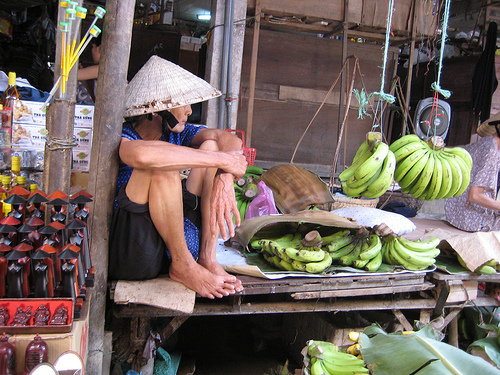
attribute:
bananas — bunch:
[330, 129, 400, 202]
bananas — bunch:
[331, 124, 401, 211]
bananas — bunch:
[330, 124, 406, 207]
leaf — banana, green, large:
[384, 127, 482, 204]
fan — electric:
[412, 88, 459, 148]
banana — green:
[298, 333, 379, 373]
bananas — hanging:
[383, 120, 475, 201]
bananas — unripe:
[323, 117, 405, 207]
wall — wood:
[188, 3, 414, 186]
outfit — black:
[105, 169, 227, 287]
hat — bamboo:
[113, 51, 230, 121]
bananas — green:
[262, 232, 478, 302]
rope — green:
[352, 43, 432, 115]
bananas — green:
[263, 217, 450, 243]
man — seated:
[115, 50, 277, 327]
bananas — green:
[398, 134, 481, 192]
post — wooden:
[91, 35, 140, 260]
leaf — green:
[355, 331, 475, 373]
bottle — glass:
[3, 73, 17, 109]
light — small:
[200, 5, 227, 41]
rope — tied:
[42, 119, 82, 172]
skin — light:
[122, 122, 205, 232]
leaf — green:
[352, 353, 482, 371]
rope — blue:
[371, 60, 409, 119]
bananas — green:
[258, 221, 436, 256]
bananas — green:
[410, 136, 468, 192]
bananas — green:
[223, 225, 358, 281]